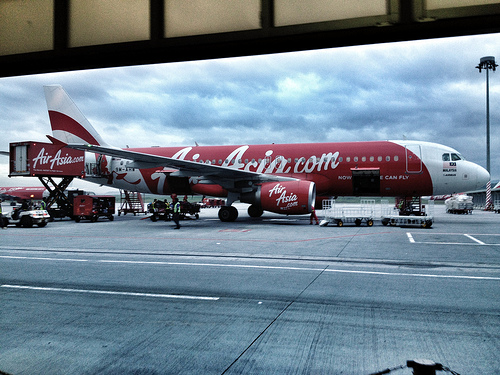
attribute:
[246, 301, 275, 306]
spot — white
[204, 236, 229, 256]
mark — white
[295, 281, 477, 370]
pavement — grey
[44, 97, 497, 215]
plane — red, large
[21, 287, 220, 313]
line — white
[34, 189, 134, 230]
cart — full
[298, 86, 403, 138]
clouds — white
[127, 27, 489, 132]
sky — cloudy